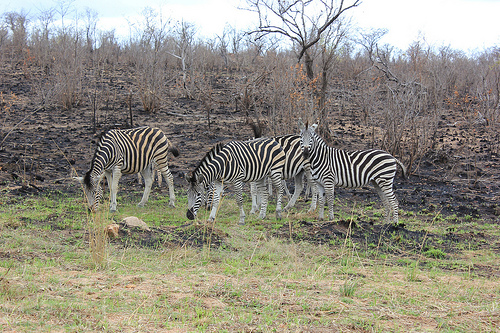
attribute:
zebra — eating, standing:
[73, 126, 180, 213]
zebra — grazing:
[186, 137, 286, 226]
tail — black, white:
[396, 157, 408, 179]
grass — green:
[1, 190, 499, 332]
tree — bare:
[237, 1, 363, 80]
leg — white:
[151, 153, 175, 206]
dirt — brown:
[108, 220, 237, 246]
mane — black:
[83, 128, 111, 188]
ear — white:
[308, 119, 320, 131]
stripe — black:
[357, 151, 389, 186]